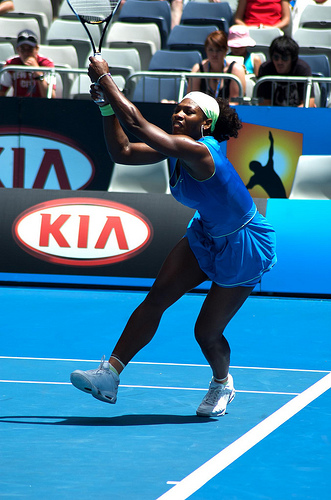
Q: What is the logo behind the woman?
A: KIA cars.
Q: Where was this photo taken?
A: On a tennis court.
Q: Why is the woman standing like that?
A: To hit the ball.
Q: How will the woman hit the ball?
A: With the racket.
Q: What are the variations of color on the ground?
A: Blue and white.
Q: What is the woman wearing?
A: Tank and tennis skirt.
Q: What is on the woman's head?
A: A scarf.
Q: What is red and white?
A: The sign.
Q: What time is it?
A: Afternoon.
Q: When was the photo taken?
A: During the daytime.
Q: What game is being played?
A: Tennis.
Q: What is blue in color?
A: The court.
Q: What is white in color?
A: The lines.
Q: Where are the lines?
A: On the court.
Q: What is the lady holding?
A: A racket.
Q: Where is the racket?
A: In lady's hands.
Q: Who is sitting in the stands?
A: Spectators.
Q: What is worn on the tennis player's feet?
A: White sneakers.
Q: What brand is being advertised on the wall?
A: Kia.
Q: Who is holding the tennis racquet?
A: The woman in blue.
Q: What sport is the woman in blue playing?
A: Tennis.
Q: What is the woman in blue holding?
A: A tennis racquet.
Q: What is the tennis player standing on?
A: A blue tennis court.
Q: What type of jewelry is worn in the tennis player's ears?
A: Silver earrings.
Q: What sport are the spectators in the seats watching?
A: Tennis.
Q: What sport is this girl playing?
A: Tennis.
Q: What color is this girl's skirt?
A: Blue.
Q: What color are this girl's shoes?
A: White.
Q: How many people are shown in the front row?
A: Three.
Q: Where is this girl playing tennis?
A: On a tennis court.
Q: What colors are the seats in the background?
A: White and blue.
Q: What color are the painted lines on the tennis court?
A: White.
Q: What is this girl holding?
A: A tennis racket.